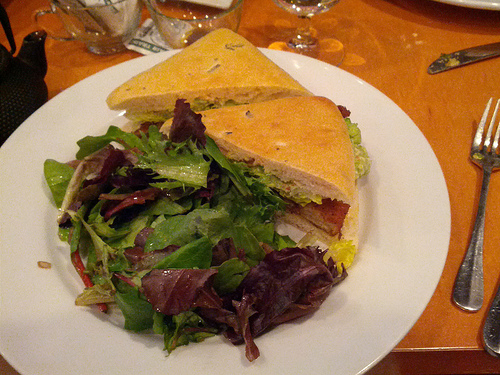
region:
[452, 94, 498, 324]
Silver fork on the table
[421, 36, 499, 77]
Dirty knife on the table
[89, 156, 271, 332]
Green and purple lettuce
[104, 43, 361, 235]
Sandwich cut in half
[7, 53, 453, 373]
White plate with food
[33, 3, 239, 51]
Two glasses on table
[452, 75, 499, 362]
Pair of silverware on the table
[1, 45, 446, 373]
White plate on table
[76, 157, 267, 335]
salad on the white plate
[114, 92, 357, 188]
Sandwich on rye bread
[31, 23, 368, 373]
sandwich and salad on plate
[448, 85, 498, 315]
one shiny silver fork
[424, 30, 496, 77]
tip of shiny silver knife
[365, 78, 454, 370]
rounded edge of white plate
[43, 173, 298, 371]
salad leaves on plate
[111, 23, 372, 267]
pointy sandwich halves next to salad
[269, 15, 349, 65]
bottom of clear wine glass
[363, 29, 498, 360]
utensils on wooden table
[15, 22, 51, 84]
dark tea kettle spout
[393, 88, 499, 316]
fork next to white plate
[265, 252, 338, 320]
purple lettuce on plate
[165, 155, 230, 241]
green lettuce on plate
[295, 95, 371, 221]
sandwich on a plate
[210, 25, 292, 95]
sandwich on a plate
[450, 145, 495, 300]
fork on a table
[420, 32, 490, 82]
knife on a table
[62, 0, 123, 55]
cup on a table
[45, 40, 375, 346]
food on a plate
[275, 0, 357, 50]
glass on a table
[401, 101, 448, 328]
plate on a table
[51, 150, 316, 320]
The green lettuce on the plate.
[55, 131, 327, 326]
The purple lettuce on the plate.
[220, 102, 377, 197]
The lettuce on the sandwich.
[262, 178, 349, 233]
The meat on the sandwich.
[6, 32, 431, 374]
The white plate the food was on.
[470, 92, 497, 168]
The points on the fork.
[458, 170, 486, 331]
The handle on the fork.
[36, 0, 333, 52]
The glasses on the table.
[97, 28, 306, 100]
The top piece of bread on the sandwich on the left.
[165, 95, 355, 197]
The top piece of bread on the sandwich on the right.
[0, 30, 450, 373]
Food on a white plate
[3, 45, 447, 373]
White plate on brown surface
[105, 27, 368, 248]
Two pieces of sandwich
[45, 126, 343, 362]
Green and purple leaves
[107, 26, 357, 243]
Sandwiches on a plate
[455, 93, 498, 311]
Silver fork on table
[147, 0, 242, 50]
Glass beside white plate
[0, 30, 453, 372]
Plate of food on table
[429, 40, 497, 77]
Sharp end of a knife